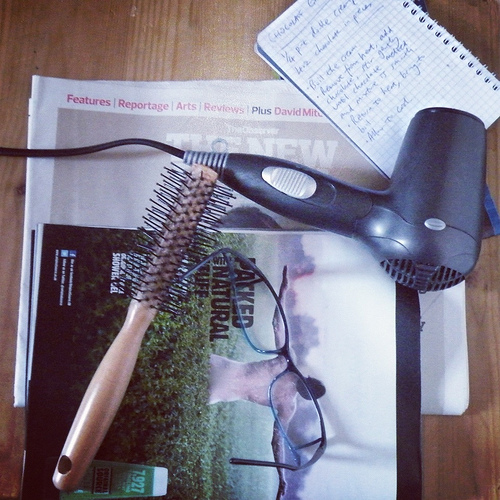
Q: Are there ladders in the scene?
A: No, there are no ladders.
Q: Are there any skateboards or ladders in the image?
A: No, there are no ladders or skateboards.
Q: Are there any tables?
A: Yes, there is a table.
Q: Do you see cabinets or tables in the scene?
A: Yes, there is a table.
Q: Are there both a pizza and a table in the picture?
A: No, there is a table but no pizzas.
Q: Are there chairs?
A: No, there are no chairs.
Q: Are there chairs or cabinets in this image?
A: No, there are no chairs or cabinets.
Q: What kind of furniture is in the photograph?
A: The furniture is a table.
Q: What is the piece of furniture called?
A: The piece of furniture is a table.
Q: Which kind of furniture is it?
A: The piece of furniture is a table.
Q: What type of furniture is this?
A: This is a table.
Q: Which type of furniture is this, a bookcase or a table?
A: This is a table.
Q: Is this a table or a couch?
A: This is a table.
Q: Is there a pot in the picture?
A: No, there are no pots.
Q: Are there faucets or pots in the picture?
A: No, there are no pots or faucets.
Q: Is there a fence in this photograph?
A: No, there are no fences.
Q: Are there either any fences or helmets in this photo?
A: No, there are no fences or helmets.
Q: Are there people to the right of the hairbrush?
A: Yes, there is a person to the right of the hairbrush.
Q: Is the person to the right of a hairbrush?
A: Yes, the person is to the right of a hairbrush.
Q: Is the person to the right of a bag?
A: No, the person is to the right of a hairbrush.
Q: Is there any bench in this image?
A: No, there are no benches.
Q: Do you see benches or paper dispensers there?
A: No, there are no benches or paper dispensers.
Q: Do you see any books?
A: No, there are no books.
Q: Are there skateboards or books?
A: No, there are no books or skateboards.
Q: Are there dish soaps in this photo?
A: No, there are no dish soaps.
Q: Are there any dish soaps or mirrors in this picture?
A: No, there are no dish soaps or mirrors.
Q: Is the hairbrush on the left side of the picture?
A: Yes, the hairbrush is on the left of the image.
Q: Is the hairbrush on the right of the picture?
A: No, the hairbrush is on the left of the image.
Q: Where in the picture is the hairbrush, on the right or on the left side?
A: The hairbrush is on the left of the image.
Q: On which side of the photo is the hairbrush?
A: The hairbrush is on the left of the image.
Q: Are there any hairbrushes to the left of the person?
A: Yes, there is a hairbrush to the left of the person.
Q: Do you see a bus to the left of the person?
A: No, there is a hairbrush to the left of the person.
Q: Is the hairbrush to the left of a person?
A: Yes, the hairbrush is to the left of a person.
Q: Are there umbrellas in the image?
A: No, there are no umbrellas.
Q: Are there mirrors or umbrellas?
A: No, there are no umbrellas or mirrors.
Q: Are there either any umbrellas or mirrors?
A: No, there are no umbrellas or mirrors.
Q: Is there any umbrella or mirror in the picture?
A: No, there are no umbrellas or mirrors.